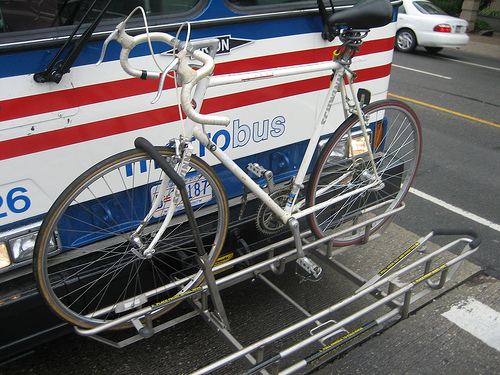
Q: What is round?
A: Wheels.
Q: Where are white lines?
A: On the street.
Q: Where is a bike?
A: Attached to the bus.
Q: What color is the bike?
A: White.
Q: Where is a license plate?
A: On bus.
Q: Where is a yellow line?
A: On street.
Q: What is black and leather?
A: Bike seat.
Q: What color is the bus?
A: Red, white and blue.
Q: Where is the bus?
A: In the front of a bus.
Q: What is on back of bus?
A: White bicycle.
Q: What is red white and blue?
A: Front of bus.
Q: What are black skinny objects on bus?
A: Windshield wipers.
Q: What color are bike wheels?
A: Black.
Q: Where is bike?
A: In bike rack.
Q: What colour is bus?
A: Red white and blue.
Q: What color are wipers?
A: Black.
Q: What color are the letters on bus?
A: Blue and white.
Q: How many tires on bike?
A: 2.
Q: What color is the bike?
A: White.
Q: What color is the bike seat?
A: Black.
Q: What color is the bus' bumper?
A: Black.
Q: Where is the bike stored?
A: Bike rack.